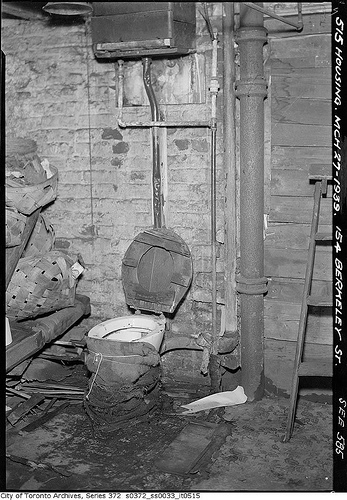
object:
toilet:
[82, 223, 193, 439]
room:
[0, 18, 333, 490]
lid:
[120, 225, 193, 316]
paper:
[180, 384, 248, 416]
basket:
[5, 250, 85, 325]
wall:
[281, 235, 294, 298]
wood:
[19, 365, 68, 418]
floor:
[65, 413, 84, 452]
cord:
[86, 349, 141, 364]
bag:
[83, 335, 162, 424]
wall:
[264, 363, 290, 394]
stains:
[101, 127, 130, 169]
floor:
[149, 421, 218, 476]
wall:
[185, 292, 208, 348]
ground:
[199, 414, 258, 464]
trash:
[16, 205, 82, 389]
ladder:
[280, 181, 334, 443]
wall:
[281, 104, 296, 201]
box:
[89, 0, 198, 64]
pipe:
[140, 55, 169, 225]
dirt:
[78, 419, 171, 460]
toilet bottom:
[83, 378, 163, 431]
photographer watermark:
[2, 469, 27, 487]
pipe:
[141, 56, 163, 228]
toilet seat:
[87, 313, 168, 346]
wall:
[2, 21, 239, 355]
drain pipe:
[232, 0, 271, 397]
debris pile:
[0, 137, 106, 471]